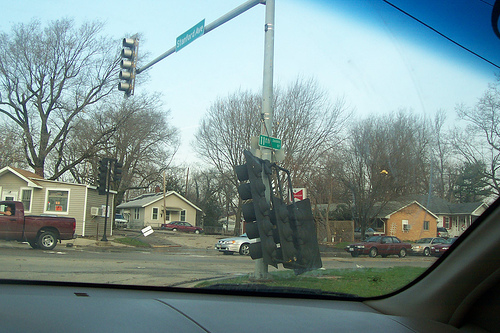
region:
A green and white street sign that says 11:
[258, 132, 283, 152]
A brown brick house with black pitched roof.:
[312, 199, 437, 241]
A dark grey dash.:
[1, 279, 433, 332]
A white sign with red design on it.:
[286, 184, 308, 201]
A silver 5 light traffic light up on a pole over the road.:
[116, 34, 138, 96]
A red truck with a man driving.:
[0, 198, 77, 250]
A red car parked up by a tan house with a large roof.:
[160, 221, 205, 236]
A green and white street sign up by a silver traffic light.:
[171, 17, 207, 51]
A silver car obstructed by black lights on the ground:
[213, 232, 258, 253]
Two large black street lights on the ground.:
[233, 151, 322, 273]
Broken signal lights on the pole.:
[230, 133, 332, 278]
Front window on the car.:
[2, 0, 498, 296]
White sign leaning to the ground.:
[125, 220, 157, 242]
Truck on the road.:
[0, 193, 79, 254]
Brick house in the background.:
[309, 194, 436, 250]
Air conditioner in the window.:
[398, 217, 414, 234]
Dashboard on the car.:
[0, 280, 465, 331]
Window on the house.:
[148, 203, 161, 222]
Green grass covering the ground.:
[195, 259, 428, 294]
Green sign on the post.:
[251, 129, 286, 155]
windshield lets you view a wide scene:
[0, 84, 465, 300]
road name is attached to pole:
[163, 18, 215, 52]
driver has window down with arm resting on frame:
[0, 197, 78, 247]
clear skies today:
[283, 19, 403, 79]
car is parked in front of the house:
[155, 214, 204, 234]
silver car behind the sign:
[210, 234, 282, 256]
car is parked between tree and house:
[352, 223, 389, 237]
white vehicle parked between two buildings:
[105, 210, 134, 229]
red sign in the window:
[37, 184, 78, 214]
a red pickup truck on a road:
[1, 198, 76, 255]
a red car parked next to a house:
[160, 217, 205, 232]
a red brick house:
[313, 200, 443, 240]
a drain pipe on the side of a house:
[378, 212, 388, 237]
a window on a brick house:
[422, 219, 432, 234]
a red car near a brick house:
[345, 229, 414, 261]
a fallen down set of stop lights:
[230, 152, 330, 276]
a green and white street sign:
[173, 13, 210, 51]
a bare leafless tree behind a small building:
[0, 18, 141, 180]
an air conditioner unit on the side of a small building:
[87, 204, 104, 219]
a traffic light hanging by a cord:
[233, 135, 341, 294]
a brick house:
[374, 203, 429, 240]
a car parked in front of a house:
[155, 216, 205, 239]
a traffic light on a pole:
[93, 11, 228, 115]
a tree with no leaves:
[16, 18, 106, 168]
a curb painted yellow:
[157, 234, 188, 253]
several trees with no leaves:
[300, 125, 461, 178]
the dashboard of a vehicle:
[0, 243, 371, 331]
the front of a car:
[215, 230, 253, 256]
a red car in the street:
[345, 227, 401, 257]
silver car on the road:
[212, 226, 266, 255]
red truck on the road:
[0, 193, 85, 256]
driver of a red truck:
[1, 204, 14, 219]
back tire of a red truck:
[32, 227, 58, 252]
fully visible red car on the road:
[341, 233, 417, 262]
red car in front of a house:
[158, 218, 207, 236]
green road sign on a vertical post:
[256, 130, 287, 152]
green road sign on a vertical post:
[174, 17, 206, 54]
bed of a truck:
[24, 210, 79, 239]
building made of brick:
[296, 196, 443, 253]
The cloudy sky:
[7, 3, 496, 194]